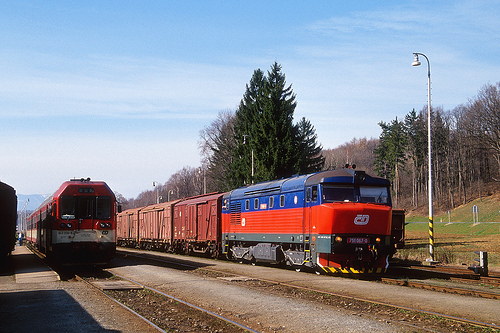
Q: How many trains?
A: Two.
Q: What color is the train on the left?
A: Red and White.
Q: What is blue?
A: Sky.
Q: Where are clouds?
A: In the sky.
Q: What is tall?
A: Trees.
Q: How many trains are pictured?
A: Two.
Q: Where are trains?
A: On train tracks.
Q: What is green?
A: Grass.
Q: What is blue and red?
A: Train on right.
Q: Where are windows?
A: On trains.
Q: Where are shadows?
A: On the ground.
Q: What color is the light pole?
A: Silver.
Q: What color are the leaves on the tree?
A: Green.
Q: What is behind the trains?
A: Trees.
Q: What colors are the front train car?
A: Blue and red.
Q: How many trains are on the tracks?
A: Two.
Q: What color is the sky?
A: Blue.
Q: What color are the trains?
A: Red and blue.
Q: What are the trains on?
A: Train tracks.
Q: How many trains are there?
A: Two.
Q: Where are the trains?
A: On the train tracks.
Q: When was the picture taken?
A: Daytime.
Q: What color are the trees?
A: Green.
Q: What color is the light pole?
A: Silver.